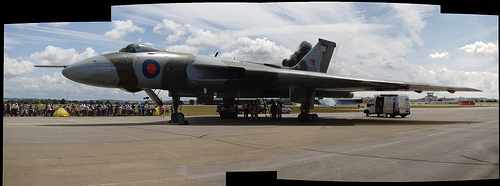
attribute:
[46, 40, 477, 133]
jet — big, old, painted, grey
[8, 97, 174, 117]
people — crowd, standing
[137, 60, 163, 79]
bullseye — orange, red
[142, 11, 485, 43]
sky — cloudy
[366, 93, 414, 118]
van — white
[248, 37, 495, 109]
wing — long